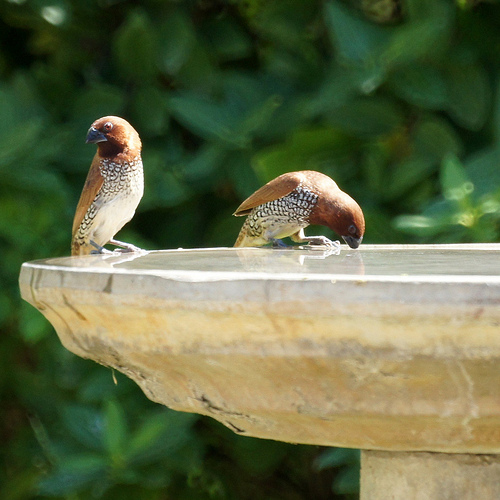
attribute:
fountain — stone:
[21, 236, 498, 498]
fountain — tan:
[47, 247, 492, 463]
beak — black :
[74, 127, 109, 152]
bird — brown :
[226, 168, 368, 253]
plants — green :
[0, 0, 499, 499]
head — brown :
[80, 109, 145, 163]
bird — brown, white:
[44, 103, 219, 281]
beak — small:
[79, 121, 111, 148]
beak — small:
[335, 231, 368, 255]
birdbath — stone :
[19, 234, 498, 453]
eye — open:
[92, 121, 122, 134]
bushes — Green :
[238, 5, 441, 139]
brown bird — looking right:
[77, 114, 161, 263]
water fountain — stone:
[16, 241, 499, 492]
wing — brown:
[188, 163, 355, 215]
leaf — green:
[168, 97, 252, 151]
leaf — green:
[155, 6, 193, 76]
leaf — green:
[237, 3, 328, 68]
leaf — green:
[110, 10, 163, 87]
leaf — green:
[66, 88, 124, 126]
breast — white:
[99, 165, 145, 236]